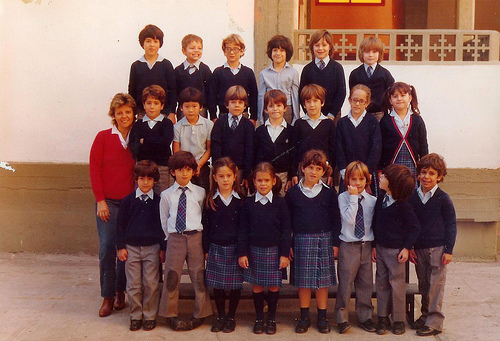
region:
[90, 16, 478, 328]
a class picturea class of kids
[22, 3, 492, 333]
a class picture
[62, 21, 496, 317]
a class of kids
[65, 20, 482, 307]
kids in uniform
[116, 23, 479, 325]
girls wearing skirts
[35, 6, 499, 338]
boys wearing khakis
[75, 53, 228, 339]
a teacher in a red shirt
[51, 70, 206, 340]
a teach wearing a long sleeve shirt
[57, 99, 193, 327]
a teach wearing jeans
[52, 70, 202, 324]
a teach wearing boots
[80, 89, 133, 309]
lady with red sweater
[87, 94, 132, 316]
lady with blue denim jeans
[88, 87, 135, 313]
lady with blonder hair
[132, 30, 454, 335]
class with kids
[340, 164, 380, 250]
boy with finger in his mouth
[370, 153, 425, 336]
boy turning his head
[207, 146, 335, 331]
three girls with skirts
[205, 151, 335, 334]
three girls with pig tails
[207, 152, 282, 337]
two girls with long black socks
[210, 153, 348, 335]
three girls with navy blue sweaters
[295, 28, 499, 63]
section of concrete decorative fence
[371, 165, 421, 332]
kid in front row looking behind him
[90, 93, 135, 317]
woman in a red shirt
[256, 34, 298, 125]
kid without sweater in the back row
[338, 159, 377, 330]
kid in frontholding up his fist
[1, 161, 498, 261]
darker brown lower section of the wall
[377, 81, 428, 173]
girl in middle row with red outline on sweater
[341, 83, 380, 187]
girl in middle row with glasses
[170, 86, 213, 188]
kid in middle row with short sleeves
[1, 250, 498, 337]
concrete ground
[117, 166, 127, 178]
WOMAN IS WEARING A RED SWEATER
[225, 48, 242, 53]
BOY IS WEARING EYE GLASSES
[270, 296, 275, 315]
GIRL HAS ON LONG BLACK SOCK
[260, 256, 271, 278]
GIRL IS WEARING A PLAID SKIRT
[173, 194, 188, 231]
BOY IS WEARING A LONG NECK TIE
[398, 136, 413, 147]
GIRL SWEATER IS CLOSED UP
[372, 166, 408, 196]
BOY HEAD IS TURN TO THE BACK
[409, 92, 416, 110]
LITTLE GIRL IS WEARING PONYTAIL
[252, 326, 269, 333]
GIRL IS WEARING BLACK SHOE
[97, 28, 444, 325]
GROUP PICTURE IS TAKEN ON PAVEMENT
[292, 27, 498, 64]
Fancy concrete grillwork on top of white wall.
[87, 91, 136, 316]
Woman in red sweater and jeans.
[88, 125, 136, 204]
Long-sleeved red sweater over white shirt.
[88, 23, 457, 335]
Group of young people with one adult.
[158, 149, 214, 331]
Young boy standing on sides of feet.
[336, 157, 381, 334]
Blond boy in white shirt, blue patterned tie, and khaki pants.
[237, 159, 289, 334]
Little girl in blue sweater and plaid skirt.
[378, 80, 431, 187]
Little girl with pigtails.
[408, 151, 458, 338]
Young boy wearing blue sweater over white shirt.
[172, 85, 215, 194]
Asian boy in short-sleeved white shirt.